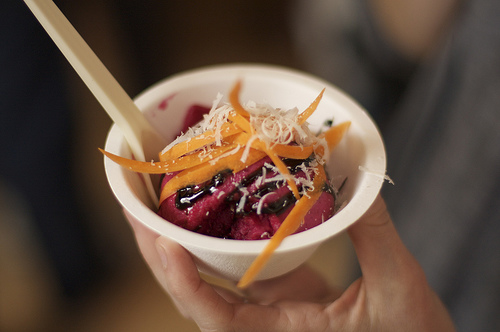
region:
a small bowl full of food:
[95, 67, 385, 247]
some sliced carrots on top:
[128, 82, 326, 251]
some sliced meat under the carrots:
[163, 149, 295, 226]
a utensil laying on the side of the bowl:
[22, 0, 182, 186]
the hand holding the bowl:
[118, 208, 448, 329]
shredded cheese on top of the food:
[243, 103, 299, 148]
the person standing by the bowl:
[284, 6, 497, 325]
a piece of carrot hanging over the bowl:
[237, 238, 289, 290]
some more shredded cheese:
[182, 101, 238, 132]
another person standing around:
[15, 71, 103, 298]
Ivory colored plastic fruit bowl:
[102, 63, 387, 282]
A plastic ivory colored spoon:
[23, 0, 160, 207]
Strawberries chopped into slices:
[160, 150, 336, 240]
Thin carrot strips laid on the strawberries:
[95, 80, 350, 289]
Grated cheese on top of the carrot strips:
[157, 93, 344, 214]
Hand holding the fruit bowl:
[122, 194, 459, 330]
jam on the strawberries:
[175, 173, 227, 210]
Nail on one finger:
[154, 242, 165, 265]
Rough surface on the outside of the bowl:
[184, 250, 322, 288]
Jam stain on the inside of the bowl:
[160, 94, 175, 111]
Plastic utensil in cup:
[26, 0, 180, 182]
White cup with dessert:
[89, 51, 393, 285]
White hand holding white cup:
[107, 47, 460, 330]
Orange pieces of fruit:
[98, 72, 354, 299]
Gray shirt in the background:
[282, 0, 498, 329]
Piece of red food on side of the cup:
[148, 85, 190, 117]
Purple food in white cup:
[157, 158, 266, 231]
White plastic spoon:
[22, 0, 189, 203]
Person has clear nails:
[148, 238, 175, 278]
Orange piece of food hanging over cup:
[232, 188, 321, 295]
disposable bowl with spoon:
[13, 9, 408, 283]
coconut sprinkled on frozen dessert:
[104, 59, 379, 268]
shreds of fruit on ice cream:
[87, 57, 399, 293]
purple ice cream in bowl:
[91, 72, 435, 272]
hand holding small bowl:
[73, 45, 437, 327]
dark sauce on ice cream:
[90, 60, 394, 282]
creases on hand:
[306, 269, 403, 330]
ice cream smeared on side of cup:
[124, 53, 207, 115]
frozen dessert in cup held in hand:
[96, 68, 390, 275]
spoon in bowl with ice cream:
[16, 11, 408, 288]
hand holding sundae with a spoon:
[20, 0, 460, 327]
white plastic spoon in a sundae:
[15, 0, 172, 210]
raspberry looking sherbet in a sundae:
[155, 110, 341, 237]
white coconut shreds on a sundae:
[242, 100, 313, 148]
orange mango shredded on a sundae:
[102, 88, 354, 285]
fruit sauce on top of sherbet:
[171, 139, 338, 216]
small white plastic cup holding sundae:
[97, 61, 393, 285]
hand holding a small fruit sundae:
[121, 187, 460, 326]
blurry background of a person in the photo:
[2, 1, 493, 326]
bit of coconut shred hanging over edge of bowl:
[355, 161, 396, 189]